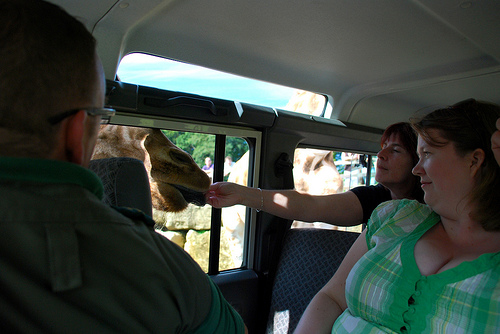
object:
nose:
[196, 176, 212, 187]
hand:
[206, 181, 248, 208]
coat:
[349, 183, 410, 235]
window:
[104, 116, 253, 274]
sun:
[270, 310, 289, 334]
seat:
[260, 226, 355, 332]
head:
[93, 116, 214, 214]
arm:
[243, 184, 378, 227]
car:
[0, 0, 500, 334]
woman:
[204, 121, 424, 228]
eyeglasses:
[72, 104, 116, 132]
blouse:
[327, 200, 499, 333]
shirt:
[0, 161, 251, 334]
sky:
[101, 56, 333, 119]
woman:
[288, 97, 500, 334]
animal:
[91, 123, 212, 213]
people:
[205, 123, 421, 233]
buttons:
[415, 291, 423, 296]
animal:
[226, 144, 349, 264]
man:
[0, 0, 248, 334]